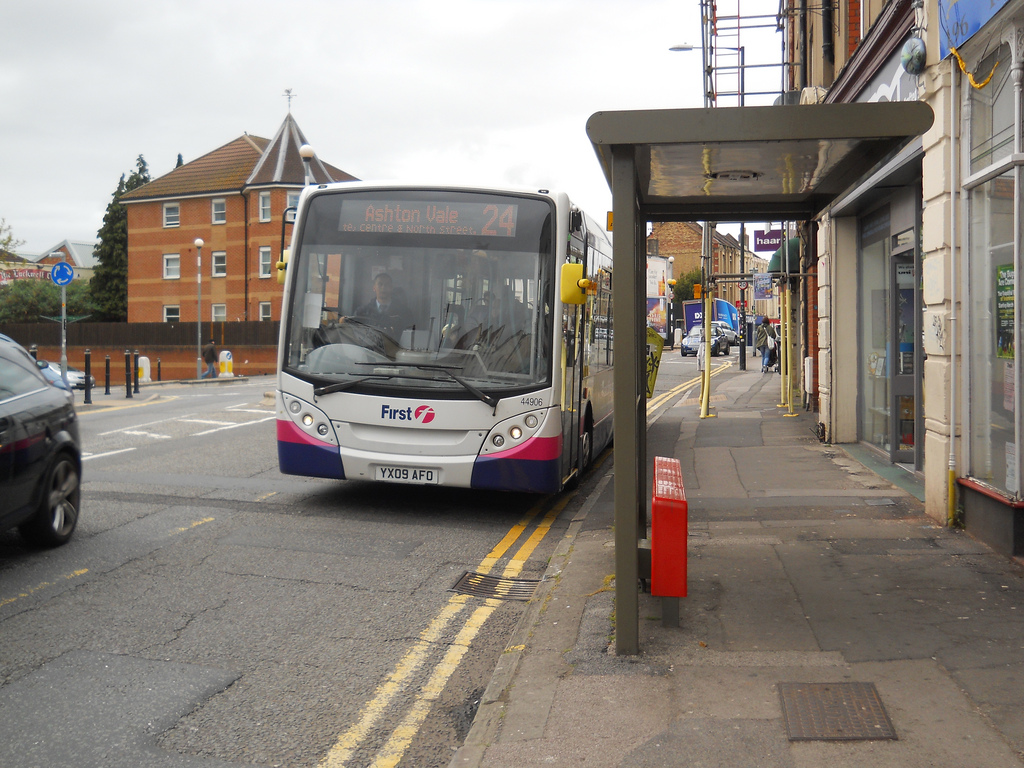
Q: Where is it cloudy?
A: In the sky.